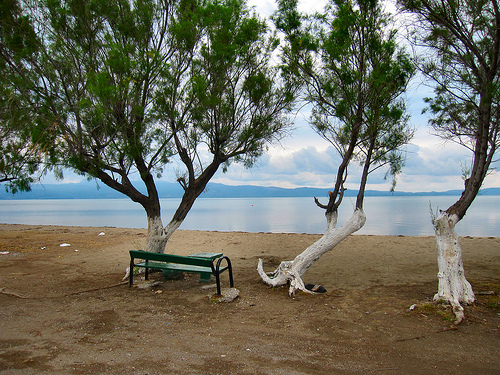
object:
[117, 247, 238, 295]
park bench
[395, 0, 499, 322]
tree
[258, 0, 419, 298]
tree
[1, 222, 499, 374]
beach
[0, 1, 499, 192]
sky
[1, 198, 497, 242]
water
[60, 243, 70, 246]
trash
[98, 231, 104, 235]
trash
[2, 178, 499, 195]
mountains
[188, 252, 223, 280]
table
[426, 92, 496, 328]
trunk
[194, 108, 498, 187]
cloud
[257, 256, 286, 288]
root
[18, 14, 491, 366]
park